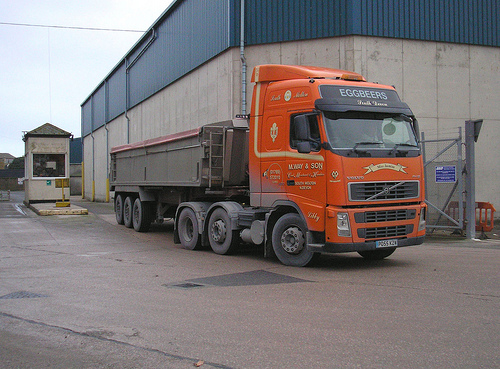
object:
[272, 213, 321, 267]
wheel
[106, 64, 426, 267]
truck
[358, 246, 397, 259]
wheel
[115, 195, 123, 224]
tire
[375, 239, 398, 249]
license plate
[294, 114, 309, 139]
mirror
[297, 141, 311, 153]
mirror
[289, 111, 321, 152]
window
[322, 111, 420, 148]
windshield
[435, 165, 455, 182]
sign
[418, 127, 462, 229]
fence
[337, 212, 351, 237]
headlight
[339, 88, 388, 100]
word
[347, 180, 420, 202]
grill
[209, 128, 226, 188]
ladder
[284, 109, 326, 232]
door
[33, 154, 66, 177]
window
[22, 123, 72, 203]
booth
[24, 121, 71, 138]
roof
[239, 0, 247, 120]
pipe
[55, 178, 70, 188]
sign